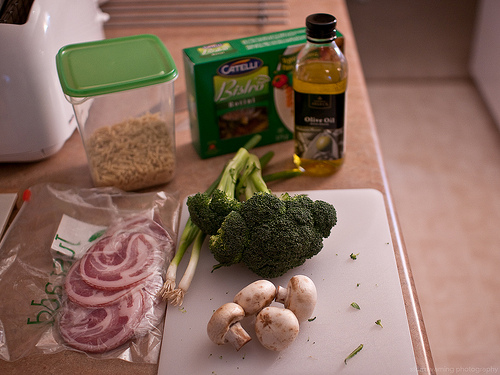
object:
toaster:
[0, 0, 110, 162]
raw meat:
[59, 215, 175, 353]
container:
[55, 34, 180, 192]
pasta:
[84, 111, 175, 191]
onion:
[95, 243, 186, 314]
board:
[156, 188, 419, 375]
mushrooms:
[191, 274, 323, 372]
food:
[186, 147, 338, 279]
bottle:
[293, 13, 349, 178]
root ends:
[160, 258, 200, 307]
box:
[181, 27, 344, 160]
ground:
[310, 70, 346, 107]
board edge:
[385, 189, 434, 375]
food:
[54, 12, 348, 352]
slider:
[22, 189, 32, 200]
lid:
[56, 34, 179, 97]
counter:
[0, 0, 436, 375]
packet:
[5, 176, 179, 367]